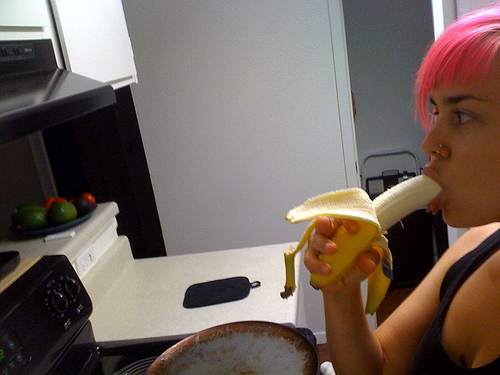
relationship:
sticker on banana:
[381, 254, 392, 279] [280, 167, 443, 315]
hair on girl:
[413, 6, 499, 134] [303, 3, 497, 374]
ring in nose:
[436, 143, 444, 157] [421, 115, 451, 163]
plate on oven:
[144, 319, 319, 374] [1, 251, 318, 375]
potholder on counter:
[181, 276, 262, 308] [87, 239, 302, 351]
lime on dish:
[46, 201, 78, 224] [10, 201, 103, 238]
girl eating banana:
[303, 3, 497, 374] [280, 167, 443, 315]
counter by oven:
[87, 239, 302, 351] [1, 251, 318, 375]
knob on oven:
[49, 288, 73, 315] [1, 251, 318, 375]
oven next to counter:
[1, 251, 318, 375] [87, 239, 302, 351]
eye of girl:
[452, 109, 475, 125] [303, 3, 497, 374]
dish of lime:
[10, 201, 103, 238] [46, 201, 78, 224]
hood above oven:
[0, 37, 117, 149] [1, 251, 318, 375]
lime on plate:
[46, 201, 78, 224] [144, 319, 319, 374]